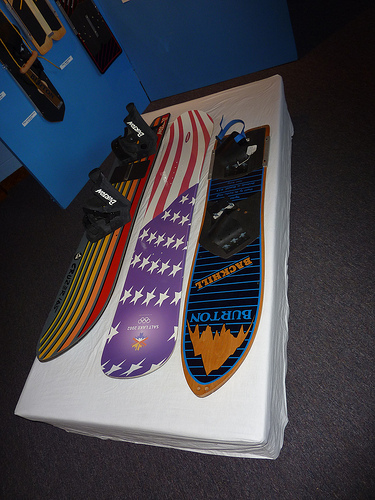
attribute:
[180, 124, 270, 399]
snowboard — pointed, black, blue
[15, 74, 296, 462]
table — white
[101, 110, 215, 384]
snowboard — red white, blue, red white blue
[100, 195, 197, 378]
stars — white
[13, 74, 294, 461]
cloth — white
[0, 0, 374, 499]
carpet — dark, gray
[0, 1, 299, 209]
wall — blue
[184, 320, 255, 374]
decal — mountain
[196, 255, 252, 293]
word — orange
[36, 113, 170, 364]
lines — yellow orange red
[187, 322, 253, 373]
mountain — orange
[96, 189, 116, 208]
word — white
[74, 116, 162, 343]
stripe — red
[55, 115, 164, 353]
stripe — orange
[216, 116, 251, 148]
footstrap — blue